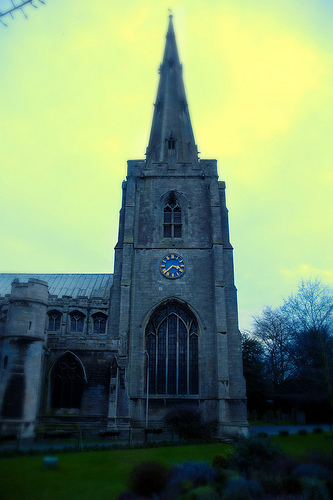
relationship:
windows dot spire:
[152, 55, 191, 153] [144, 9, 200, 172]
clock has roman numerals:
[157, 249, 186, 282] [158, 250, 187, 277]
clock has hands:
[157, 249, 186, 282] [161, 261, 180, 277]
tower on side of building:
[105, 9, 251, 448] [0, 14, 251, 440]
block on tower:
[208, 288, 241, 340] [111, 222, 247, 344]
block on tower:
[108, 282, 146, 363] [98, 181, 280, 372]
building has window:
[4, 5, 257, 440] [161, 205, 171, 240]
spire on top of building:
[147, 33, 195, 148] [155, 215, 217, 475]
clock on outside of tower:
[157, 249, 186, 282] [140, 211, 222, 400]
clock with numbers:
[152, 254, 194, 288] [166, 254, 179, 273]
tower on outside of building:
[0, 272, 46, 449] [34, 326, 99, 441]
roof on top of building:
[15, 264, 110, 296] [3, 290, 110, 375]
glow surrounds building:
[1, 2, 320, 303] [0, 14, 251, 440]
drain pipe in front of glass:
[137, 349, 150, 428] [139, 293, 200, 396]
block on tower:
[213, 332, 228, 383] [105, 3, 253, 437]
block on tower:
[210, 243, 226, 289] [105, 3, 253, 437]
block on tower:
[209, 200, 228, 250] [105, 3, 253, 437]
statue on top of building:
[164, 5, 177, 16] [4, 5, 257, 440]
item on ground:
[39, 450, 62, 465] [3, 424, 332, 498]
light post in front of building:
[140, 345, 154, 444] [4, 5, 257, 440]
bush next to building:
[158, 402, 219, 445] [4, 5, 257, 440]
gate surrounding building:
[11, 421, 189, 455] [4, 5, 257, 440]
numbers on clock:
[161, 252, 182, 279] [154, 243, 188, 282]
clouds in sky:
[0, 0, 333, 354] [1, 0, 330, 379]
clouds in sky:
[194, 16, 244, 83] [1, 0, 330, 379]